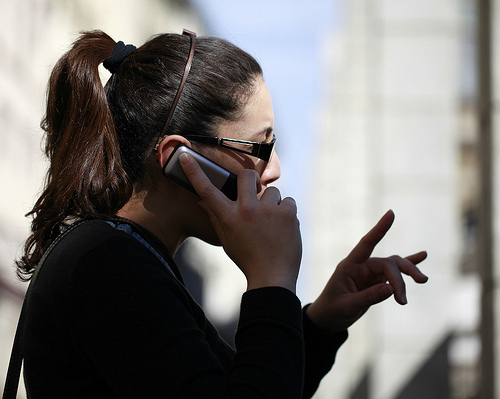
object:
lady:
[0, 28, 429, 398]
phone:
[161, 143, 237, 201]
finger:
[345, 283, 395, 313]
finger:
[403, 250, 427, 266]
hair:
[11, 28, 264, 283]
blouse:
[13, 216, 349, 399]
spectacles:
[156, 134, 277, 164]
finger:
[179, 152, 232, 221]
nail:
[179, 153, 192, 166]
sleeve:
[303, 302, 348, 399]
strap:
[2, 215, 178, 399]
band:
[151, 28, 197, 153]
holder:
[103, 41, 138, 74]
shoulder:
[61, 220, 168, 314]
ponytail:
[12, 28, 134, 283]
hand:
[178, 152, 303, 285]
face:
[191, 74, 280, 246]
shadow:
[218, 142, 256, 169]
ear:
[157, 135, 192, 188]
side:
[0, 28, 428, 398]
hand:
[307, 209, 429, 332]